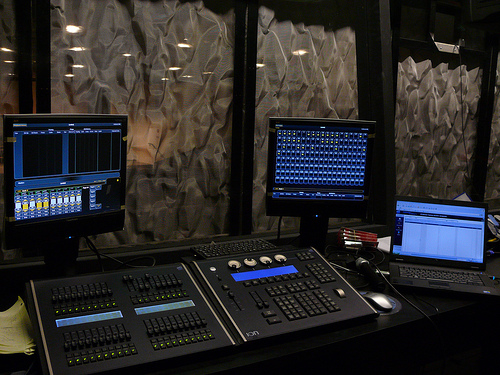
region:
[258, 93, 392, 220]
a blue computer screen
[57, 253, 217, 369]
a black machine with a lot of buttons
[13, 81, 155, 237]
a blue, black and yellow screen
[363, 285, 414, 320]
a computer mouse on the table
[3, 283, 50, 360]
some papers on the desk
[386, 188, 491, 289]
a laptop on the desk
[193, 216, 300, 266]
a black keyboard on the desk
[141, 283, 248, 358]
black and yellow knobs on a black electronic board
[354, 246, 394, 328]
a microphone on a desk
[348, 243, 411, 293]
a black microphone with a grey head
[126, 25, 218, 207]
shiny glass surface of the window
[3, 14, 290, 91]
reflections of lights on the window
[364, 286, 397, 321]
a black computer mouse on the desk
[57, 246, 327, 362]
black electonic mixing board on the desk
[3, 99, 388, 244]
two computer monitors on the desk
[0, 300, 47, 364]
yellow papers on the desk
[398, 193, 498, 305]
black laptop computer on the desk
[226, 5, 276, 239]
black wood jambs of the windows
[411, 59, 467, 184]
white soundproofing inside the window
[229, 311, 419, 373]
black wooden surface of the desk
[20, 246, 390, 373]
A sound mixer on a counter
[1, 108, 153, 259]
A computer screen showing different audio channels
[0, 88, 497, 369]
A music producers booth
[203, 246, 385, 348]
A sound mixer on a table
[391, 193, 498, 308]
A laptop computer displaying file list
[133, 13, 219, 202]
Sound proofing material on a studio wall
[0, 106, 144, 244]
Audio channels displayed on a computer screen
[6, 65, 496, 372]
Music studio equipment ready for recording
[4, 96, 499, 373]
A sound studio ready for mixing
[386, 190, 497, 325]
A laptop computer with program running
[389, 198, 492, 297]
an open laptop computer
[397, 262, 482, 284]
a black computer keyboard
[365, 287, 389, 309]
a silver corded mouse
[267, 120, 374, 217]
a black computer monitor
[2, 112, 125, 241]
a black computer monitor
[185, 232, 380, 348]
a black mixing board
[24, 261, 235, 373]
a black mixing board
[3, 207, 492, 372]
a long black desk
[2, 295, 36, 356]
a piece of paper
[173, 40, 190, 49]
reflection of a light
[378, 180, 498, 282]
a monitor in a control room.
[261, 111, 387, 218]
a monitor behind a monitor.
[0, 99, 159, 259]
a monitor with icons on it.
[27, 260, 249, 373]
a monitor in a sound room.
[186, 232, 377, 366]
an advanced sound board.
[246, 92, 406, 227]
a monitor near a window.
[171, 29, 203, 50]
light reflecting on a window.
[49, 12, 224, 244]
a window with lights reflecting on it.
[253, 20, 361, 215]
a large window with light reflecting on it.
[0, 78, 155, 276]
a control panel on a monitor.